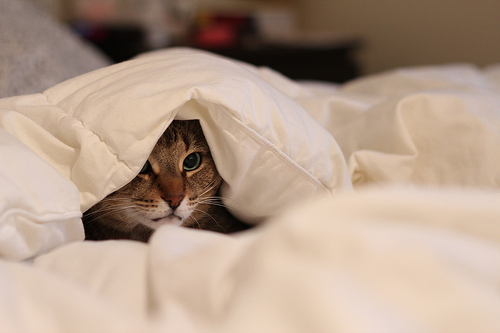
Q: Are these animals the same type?
A: Yes, all the animals are cats.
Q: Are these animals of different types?
A: No, all the animals are cats.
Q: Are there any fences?
A: No, there are no fences.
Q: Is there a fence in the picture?
A: No, there are no fences.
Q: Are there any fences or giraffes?
A: No, there are no fences or giraffes.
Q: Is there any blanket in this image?
A: Yes, there is a blanket.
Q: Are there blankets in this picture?
A: Yes, there is a blanket.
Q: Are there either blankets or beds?
A: Yes, there is a blanket.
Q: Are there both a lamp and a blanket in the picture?
A: No, there is a blanket but no lamps.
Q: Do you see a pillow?
A: No, there are no pillows.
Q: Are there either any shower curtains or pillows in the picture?
A: No, there are no pillows or shower curtains.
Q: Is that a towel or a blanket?
A: That is a blanket.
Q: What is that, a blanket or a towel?
A: That is a blanket.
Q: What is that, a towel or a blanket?
A: That is a blanket.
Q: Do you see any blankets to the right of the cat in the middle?
A: Yes, there is a blanket to the right of the cat.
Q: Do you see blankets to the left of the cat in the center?
A: No, the blanket is to the right of the cat.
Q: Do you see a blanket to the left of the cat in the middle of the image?
A: No, the blanket is to the right of the cat.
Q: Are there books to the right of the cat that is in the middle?
A: No, there is a blanket to the right of the cat.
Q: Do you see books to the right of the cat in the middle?
A: No, there is a blanket to the right of the cat.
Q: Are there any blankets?
A: Yes, there is a blanket.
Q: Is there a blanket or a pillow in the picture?
A: Yes, there is a blanket.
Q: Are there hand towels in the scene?
A: No, there are no hand towels.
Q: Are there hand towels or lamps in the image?
A: No, there are no hand towels or lamps.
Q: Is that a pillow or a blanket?
A: That is a blanket.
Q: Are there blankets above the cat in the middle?
A: Yes, there is a blanket above the cat.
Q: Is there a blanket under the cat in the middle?
A: No, the blanket is above the cat.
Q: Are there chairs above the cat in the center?
A: No, there is a blanket above the cat.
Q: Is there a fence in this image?
A: No, there are no fences.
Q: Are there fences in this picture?
A: No, there are no fences.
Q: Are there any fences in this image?
A: No, there are no fences.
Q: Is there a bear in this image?
A: No, there are no bears.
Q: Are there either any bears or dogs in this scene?
A: No, there are no bears or dogs.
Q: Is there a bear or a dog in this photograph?
A: No, there are no bears or dogs.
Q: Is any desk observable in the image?
A: Yes, there is a desk.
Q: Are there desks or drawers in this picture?
A: Yes, there is a desk.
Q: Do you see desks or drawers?
A: Yes, there is a desk.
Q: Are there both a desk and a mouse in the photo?
A: No, there is a desk but no computer mice.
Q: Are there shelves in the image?
A: No, there are no shelves.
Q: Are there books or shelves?
A: No, there are no shelves or books.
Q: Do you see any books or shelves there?
A: No, there are no shelves or books.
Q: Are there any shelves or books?
A: No, there are no shelves or books.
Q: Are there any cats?
A: Yes, there is a cat.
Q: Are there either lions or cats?
A: Yes, there is a cat.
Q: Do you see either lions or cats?
A: Yes, there is a cat.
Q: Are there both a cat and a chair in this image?
A: No, there is a cat but no chairs.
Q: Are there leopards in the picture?
A: No, there are no leopards.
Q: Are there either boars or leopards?
A: No, there are no leopards or boars.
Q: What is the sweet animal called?
A: The animal is a cat.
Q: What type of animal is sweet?
A: The animal is a cat.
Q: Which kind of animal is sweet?
A: The animal is a cat.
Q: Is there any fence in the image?
A: No, there are no fences.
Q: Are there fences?
A: No, there are no fences.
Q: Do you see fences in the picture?
A: No, there are no fences.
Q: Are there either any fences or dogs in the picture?
A: No, there are no fences or dogs.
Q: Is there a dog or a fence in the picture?
A: No, there are no fences or dogs.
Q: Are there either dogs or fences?
A: No, there are no fences or dogs.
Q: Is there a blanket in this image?
A: Yes, there is a blanket.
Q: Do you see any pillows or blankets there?
A: Yes, there is a blanket.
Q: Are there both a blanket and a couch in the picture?
A: No, there is a blanket but no couches.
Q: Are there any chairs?
A: No, there are no chairs.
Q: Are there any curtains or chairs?
A: No, there are no chairs or curtains.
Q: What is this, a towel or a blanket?
A: This is a blanket.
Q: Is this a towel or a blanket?
A: This is a blanket.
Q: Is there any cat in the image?
A: Yes, there is a cat.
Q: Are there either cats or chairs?
A: Yes, there is a cat.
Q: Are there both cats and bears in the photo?
A: No, there is a cat but no bears.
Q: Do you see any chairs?
A: No, there are no chairs.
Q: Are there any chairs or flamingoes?
A: No, there are no chairs or flamingoes.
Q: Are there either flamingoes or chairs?
A: No, there are no chairs or flamingoes.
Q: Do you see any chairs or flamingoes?
A: No, there are no chairs or flamingoes.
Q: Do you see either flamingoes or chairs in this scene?
A: No, there are no chairs or flamingoes.